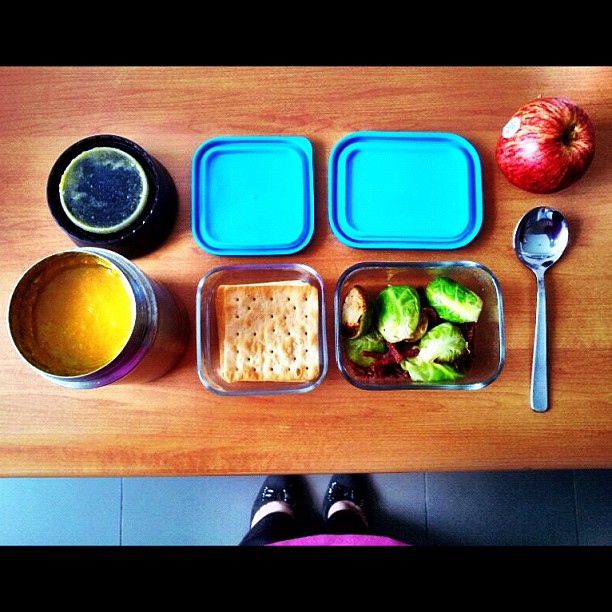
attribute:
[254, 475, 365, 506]
shoes — black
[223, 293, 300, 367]
crackers — white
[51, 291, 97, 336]
cheese — yellow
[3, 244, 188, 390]
container — silver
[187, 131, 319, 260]
lid — blue, square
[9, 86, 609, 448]
board — wooden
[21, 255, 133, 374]
soup — yellow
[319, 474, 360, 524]
dress shoe — black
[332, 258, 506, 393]
container — rectangle, glass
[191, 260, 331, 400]
container — glass, smaller, square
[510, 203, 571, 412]
spoon — silver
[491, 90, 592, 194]
apple — red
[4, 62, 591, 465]
table — Brown, wood 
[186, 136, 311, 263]
cover — blue 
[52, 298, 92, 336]
sauce — yellow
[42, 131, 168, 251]
cover — black 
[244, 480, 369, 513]
shoes — black 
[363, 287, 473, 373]
sprouts — Brussel 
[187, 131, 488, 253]
lid — blue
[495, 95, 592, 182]
apple — red  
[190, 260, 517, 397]
containers — plastic 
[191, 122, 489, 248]
lids — blue 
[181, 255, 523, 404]
containers — clear 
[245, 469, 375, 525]
shoes — black 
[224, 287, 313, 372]
crackers — clear 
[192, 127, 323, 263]
cover — blue, tupperware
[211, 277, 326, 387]
cracker — saltine